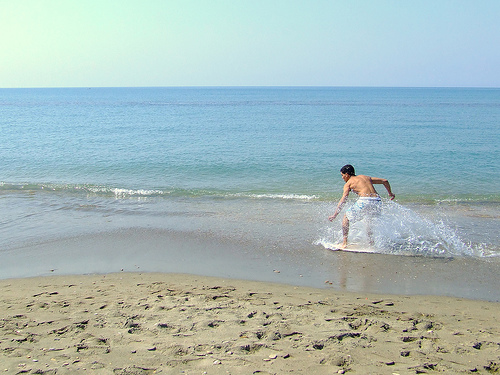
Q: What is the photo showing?
A: It is showing an ocean.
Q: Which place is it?
A: It is an ocean.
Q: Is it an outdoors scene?
A: Yes, it is outdoors.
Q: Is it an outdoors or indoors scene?
A: It is outdoors.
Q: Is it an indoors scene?
A: No, it is outdoors.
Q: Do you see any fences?
A: No, there are no fences.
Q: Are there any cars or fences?
A: No, there are no fences or cars.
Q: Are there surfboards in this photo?
A: Yes, there is a surfboard.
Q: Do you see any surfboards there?
A: Yes, there is a surfboard.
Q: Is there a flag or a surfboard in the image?
A: Yes, there is a surfboard.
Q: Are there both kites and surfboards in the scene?
A: No, there is a surfboard but no kites.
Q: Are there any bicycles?
A: No, there are no bicycles.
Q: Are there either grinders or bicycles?
A: No, there are no bicycles or grinders.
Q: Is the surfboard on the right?
A: Yes, the surfboard is on the right of the image.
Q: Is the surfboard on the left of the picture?
A: No, the surfboard is on the right of the image.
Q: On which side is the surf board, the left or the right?
A: The surf board is on the right of the image.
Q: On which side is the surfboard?
A: The surfboard is on the right of the image.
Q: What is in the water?
A: The surf board is in the water.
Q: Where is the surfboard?
A: The surfboard is in the water.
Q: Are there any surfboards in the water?
A: Yes, there is a surfboard in the water.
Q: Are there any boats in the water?
A: No, there is a surfboard in the water.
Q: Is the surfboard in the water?
A: Yes, the surfboard is in the water.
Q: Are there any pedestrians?
A: No, there are no pedestrians.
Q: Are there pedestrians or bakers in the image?
A: No, there are no pedestrians or bakers.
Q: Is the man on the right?
A: Yes, the man is on the right of the image.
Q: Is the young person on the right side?
A: Yes, the man is on the right of the image.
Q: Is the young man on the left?
A: No, the man is on the right of the image.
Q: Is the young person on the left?
A: No, the man is on the right of the image.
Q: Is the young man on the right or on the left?
A: The man is on the right of the image.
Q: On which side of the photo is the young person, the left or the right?
A: The man is on the right of the image.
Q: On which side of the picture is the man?
A: The man is on the right of the image.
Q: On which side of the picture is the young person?
A: The man is on the right of the image.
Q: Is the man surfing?
A: Yes, the man is surfing.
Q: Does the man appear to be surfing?
A: Yes, the man is surfing.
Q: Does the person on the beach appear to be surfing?
A: Yes, the man is surfing.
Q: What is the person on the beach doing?
A: The man is surfing.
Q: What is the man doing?
A: The man is surfing.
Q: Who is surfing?
A: The man is surfing.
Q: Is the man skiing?
A: No, the man is surfing.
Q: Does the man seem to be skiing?
A: No, the man is surfing.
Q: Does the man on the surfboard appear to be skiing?
A: No, the man is surfing.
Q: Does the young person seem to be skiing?
A: No, the man is surfing.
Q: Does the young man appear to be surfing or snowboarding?
A: The man is surfing.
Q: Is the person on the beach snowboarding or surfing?
A: The man is surfing.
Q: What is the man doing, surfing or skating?
A: The man is surfing.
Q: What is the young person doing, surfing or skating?
A: The man is surfing.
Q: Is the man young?
A: Yes, the man is young.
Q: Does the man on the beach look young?
A: Yes, the man is young.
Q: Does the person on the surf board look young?
A: Yes, the man is young.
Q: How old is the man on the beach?
A: The man is young.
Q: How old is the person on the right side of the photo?
A: The man is young.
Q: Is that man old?
A: No, the man is young.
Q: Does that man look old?
A: No, the man is young.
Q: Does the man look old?
A: No, the man is young.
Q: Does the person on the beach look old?
A: No, the man is young.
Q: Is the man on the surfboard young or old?
A: The man is young.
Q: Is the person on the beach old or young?
A: The man is young.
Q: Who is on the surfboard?
A: The man is on the surfboard.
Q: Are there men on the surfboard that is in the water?
A: Yes, there is a man on the surfboard.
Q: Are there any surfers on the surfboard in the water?
A: No, there is a man on the surfboard.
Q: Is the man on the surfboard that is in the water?
A: Yes, the man is on the surfboard.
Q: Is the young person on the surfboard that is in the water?
A: Yes, the man is on the surfboard.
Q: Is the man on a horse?
A: No, the man is on the surfboard.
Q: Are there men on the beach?
A: Yes, there is a man on the beach.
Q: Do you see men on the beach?
A: Yes, there is a man on the beach.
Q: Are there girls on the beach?
A: No, there is a man on the beach.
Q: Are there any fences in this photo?
A: No, there are no fences.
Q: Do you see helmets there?
A: No, there are no helmets.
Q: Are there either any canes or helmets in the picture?
A: No, there are no helmets or canes.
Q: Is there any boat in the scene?
A: No, there are no boats.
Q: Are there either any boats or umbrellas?
A: No, there are no boats or umbrellas.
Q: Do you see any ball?
A: No, there are no balls.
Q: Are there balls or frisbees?
A: No, there are no balls or frisbees.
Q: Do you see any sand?
A: Yes, there is sand.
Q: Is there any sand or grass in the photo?
A: Yes, there is sand.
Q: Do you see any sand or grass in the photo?
A: Yes, there is sand.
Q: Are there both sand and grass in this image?
A: No, there is sand but no grass.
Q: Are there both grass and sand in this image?
A: No, there is sand but no grass.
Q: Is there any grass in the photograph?
A: No, there is no grass.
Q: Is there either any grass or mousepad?
A: No, there are no grass or mouse pads.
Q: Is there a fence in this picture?
A: No, there are no fences.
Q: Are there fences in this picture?
A: No, there are no fences.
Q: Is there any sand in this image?
A: Yes, there is sand.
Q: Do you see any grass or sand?
A: Yes, there is sand.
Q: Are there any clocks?
A: No, there are no clocks.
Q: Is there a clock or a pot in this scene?
A: No, there are no clocks or pots.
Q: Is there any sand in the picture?
A: Yes, there is sand.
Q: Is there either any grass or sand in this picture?
A: Yes, there is sand.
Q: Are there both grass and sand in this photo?
A: No, there is sand but no grass.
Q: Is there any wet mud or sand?
A: Yes, there is wet sand.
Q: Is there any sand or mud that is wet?
A: Yes, the sand is wet.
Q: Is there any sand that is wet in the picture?
A: Yes, there is wet sand.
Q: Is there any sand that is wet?
A: Yes, there is sand that is wet.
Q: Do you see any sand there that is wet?
A: Yes, there is sand that is wet.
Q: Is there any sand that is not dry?
A: Yes, there is wet sand.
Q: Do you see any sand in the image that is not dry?
A: Yes, there is wet sand.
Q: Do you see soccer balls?
A: No, there are no soccer balls.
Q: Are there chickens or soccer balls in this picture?
A: No, there are no soccer balls or chickens.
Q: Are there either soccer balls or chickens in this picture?
A: No, there are no soccer balls or chickens.